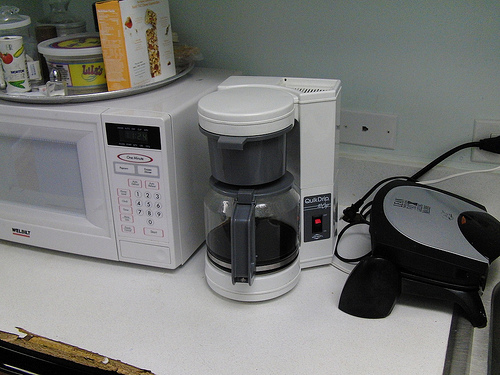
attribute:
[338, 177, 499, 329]
grill — black, silver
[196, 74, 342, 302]
coffee maker — white, empty, electric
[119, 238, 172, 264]
button — black, white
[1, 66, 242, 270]
microwave — white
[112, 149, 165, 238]
buttons — flat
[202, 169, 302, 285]
coffee pot — empty, glass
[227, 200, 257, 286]
handle — black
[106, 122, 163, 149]
display — digital, blank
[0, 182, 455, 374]
counter — white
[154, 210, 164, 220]
button — black, white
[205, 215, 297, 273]
coffee — black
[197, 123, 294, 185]
filter basket — black